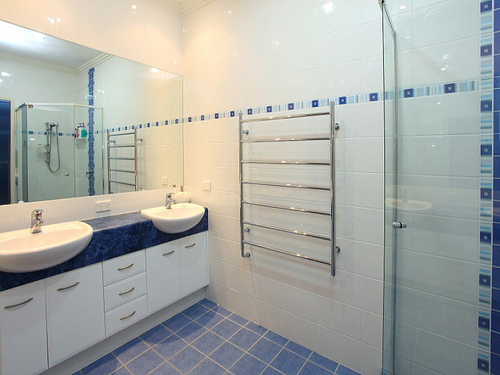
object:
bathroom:
[0, 0, 499, 375]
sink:
[137, 201, 204, 232]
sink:
[0, 221, 94, 272]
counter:
[0, 201, 208, 296]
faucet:
[161, 191, 177, 210]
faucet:
[27, 208, 45, 235]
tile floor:
[67, 297, 375, 374]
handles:
[4, 298, 34, 311]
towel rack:
[235, 111, 328, 123]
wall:
[183, 0, 499, 373]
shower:
[379, 1, 498, 374]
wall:
[0, 0, 182, 81]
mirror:
[0, 20, 184, 208]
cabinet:
[146, 231, 211, 315]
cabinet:
[0, 262, 105, 374]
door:
[0, 100, 11, 205]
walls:
[382, 2, 499, 373]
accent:
[181, 77, 478, 125]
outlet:
[95, 198, 112, 214]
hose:
[47, 126, 63, 175]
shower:
[15, 102, 105, 202]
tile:
[333, 300, 383, 351]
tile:
[334, 268, 382, 315]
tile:
[209, 258, 229, 288]